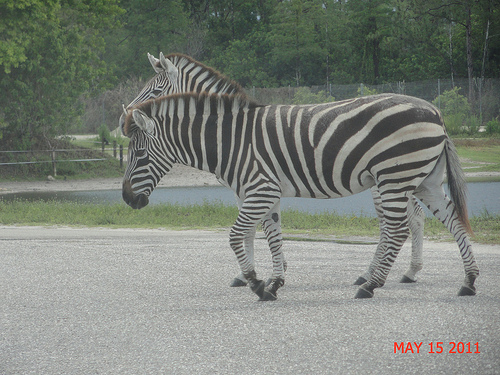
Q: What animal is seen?
A: Zebra.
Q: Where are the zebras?
A: Paved path.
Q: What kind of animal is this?
A: Zebra.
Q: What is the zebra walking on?
A: Cement street.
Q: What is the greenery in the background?
A: Trees and foliage.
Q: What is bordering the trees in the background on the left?
A: Metal fence.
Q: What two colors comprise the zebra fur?
A: Black and white.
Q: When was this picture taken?
A: May 15, 2011.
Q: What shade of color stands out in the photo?
A: Red print in the lower right hand corner.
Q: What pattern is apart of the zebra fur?
A: Stripes.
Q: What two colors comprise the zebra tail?
A: Black and grey.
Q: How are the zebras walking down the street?
A: Side by side.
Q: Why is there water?
A: For zebras to drink.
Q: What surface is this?
A: Pavement.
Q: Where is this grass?
A: Between pavement and water.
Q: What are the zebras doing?
A: Walking.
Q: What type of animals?
A: Zebras.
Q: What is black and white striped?
A: Zebras.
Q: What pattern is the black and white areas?
A: Striped.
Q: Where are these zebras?
A: Zoo.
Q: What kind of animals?
A: Zebras.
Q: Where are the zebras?
A: On the road.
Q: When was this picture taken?
A: May 15 2011.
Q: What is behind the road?
A: Grass.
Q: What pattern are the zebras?
A: Stripes.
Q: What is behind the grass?
A: Water.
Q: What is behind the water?
A: A fence.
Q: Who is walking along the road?
A: Zebras.